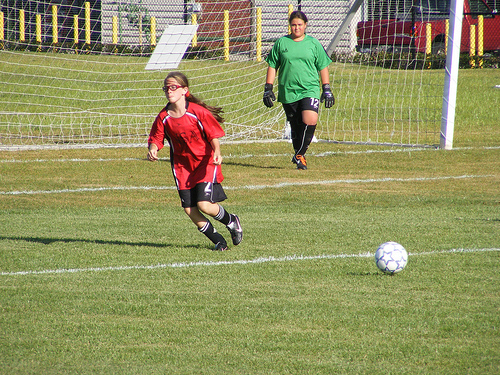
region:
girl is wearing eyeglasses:
[132, 61, 229, 148]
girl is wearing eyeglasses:
[150, 64, 190, 101]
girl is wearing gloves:
[246, 4, 361, 139]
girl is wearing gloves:
[244, 76, 375, 124]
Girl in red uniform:
[128, 62, 253, 254]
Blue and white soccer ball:
[351, 215, 428, 300]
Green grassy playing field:
[28, 285, 394, 369]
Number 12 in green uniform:
[266, 15, 340, 174]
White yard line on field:
[21, 259, 187, 286]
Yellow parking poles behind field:
[11, 9, 177, 44]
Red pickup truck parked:
[353, 5, 493, 62]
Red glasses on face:
[151, 85, 188, 95]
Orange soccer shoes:
[291, 155, 316, 170]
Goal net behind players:
[16, 3, 130, 131]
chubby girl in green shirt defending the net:
[257, 9, 342, 176]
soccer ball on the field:
[372, 238, 409, 279]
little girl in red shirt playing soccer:
[141, 70, 249, 252]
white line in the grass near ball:
[1, 244, 497, 279]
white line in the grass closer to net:
[0, 171, 498, 198]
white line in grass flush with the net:
[1, 141, 496, 166]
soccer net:
[0, 2, 449, 148]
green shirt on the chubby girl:
[265, 34, 333, 103]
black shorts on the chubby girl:
[276, 98, 320, 118]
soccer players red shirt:
[138, 98, 225, 187]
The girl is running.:
[133, 63, 259, 257]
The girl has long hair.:
[127, 68, 261, 271]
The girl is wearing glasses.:
[132, 63, 257, 260]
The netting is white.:
[3, 2, 499, 164]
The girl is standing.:
[241, 10, 354, 190]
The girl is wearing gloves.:
[258, 11, 351, 170]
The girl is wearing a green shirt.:
[249, 10, 349, 172]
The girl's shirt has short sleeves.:
[255, 7, 347, 176]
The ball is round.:
[350, 220, 417, 317]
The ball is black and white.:
[335, 231, 454, 313]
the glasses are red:
[158, 80, 183, 95]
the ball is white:
[371, 238, 411, 278]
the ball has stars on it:
[377, 249, 396, 266]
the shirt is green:
[284, 48, 309, 80]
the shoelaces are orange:
[293, 153, 307, 168]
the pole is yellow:
[418, 19, 434, 54]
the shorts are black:
[185, 184, 211, 198]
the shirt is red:
[178, 126, 200, 159]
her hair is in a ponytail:
[178, 79, 200, 104]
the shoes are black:
[222, 209, 247, 241]